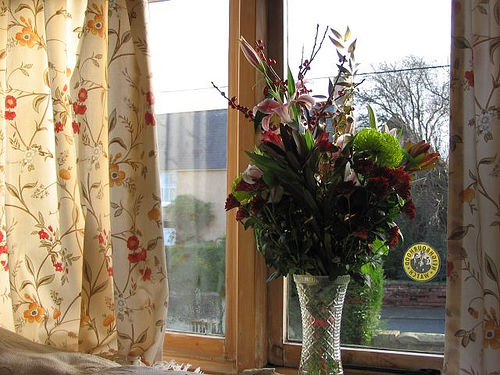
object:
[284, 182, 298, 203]
part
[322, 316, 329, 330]
part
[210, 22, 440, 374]
plant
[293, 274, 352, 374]
vase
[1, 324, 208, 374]
cloth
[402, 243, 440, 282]
circle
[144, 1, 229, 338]
window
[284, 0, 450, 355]
glass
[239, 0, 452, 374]
window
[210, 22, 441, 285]
arrangement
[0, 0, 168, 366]
curtains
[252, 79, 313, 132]
lily flower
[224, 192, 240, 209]
carnations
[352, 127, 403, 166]
flower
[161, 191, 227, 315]
hedge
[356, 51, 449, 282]
tree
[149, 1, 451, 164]
sky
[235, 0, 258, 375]
wall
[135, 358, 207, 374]
white frill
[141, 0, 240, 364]
seal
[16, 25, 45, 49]
sunflowers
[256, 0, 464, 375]
window frame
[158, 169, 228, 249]
building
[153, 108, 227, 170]
black roof